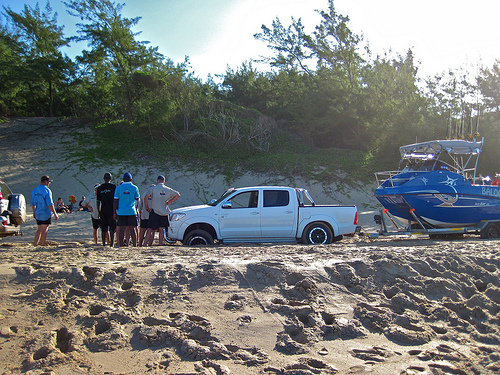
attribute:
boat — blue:
[368, 136, 497, 226]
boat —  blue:
[360, 119, 498, 261]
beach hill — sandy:
[1, 243, 498, 373]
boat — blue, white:
[359, 139, 497, 251]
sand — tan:
[0, 209, 499, 372]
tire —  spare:
[183, 232, 215, 244]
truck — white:
[177, 205, 355, 234]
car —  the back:
[0, 179, 26, 241]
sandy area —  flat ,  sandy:
[10, 237, 494, 374]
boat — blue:
[369, 137, 496, 238]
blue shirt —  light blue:
[112, 180, 141, 216]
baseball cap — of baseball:
[122, 171, 132, 183]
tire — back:
[302, 222, 339, 254]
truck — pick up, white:
[164, 182, 361, 242]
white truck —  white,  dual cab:
[166, 183, 360, 250]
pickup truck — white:
[168, 184, 358, 245]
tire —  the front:
[183, 228, 214, 245]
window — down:
[216, 189, 294, 209]